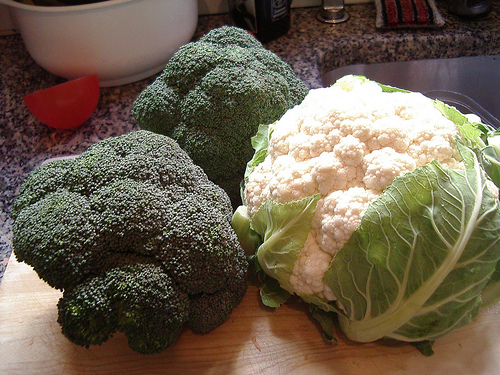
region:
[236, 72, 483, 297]
white florets of fresh cauliflower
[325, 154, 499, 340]
a dark leaf hugs the cauliflower head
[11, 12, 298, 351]
two firm heads of broccoli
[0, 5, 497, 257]
a granite counter top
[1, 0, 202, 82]
a large white bowl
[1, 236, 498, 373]
vegetables sit on a cutting board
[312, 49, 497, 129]
back wall of a kitchen sink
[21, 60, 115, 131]
a red wedge on the counter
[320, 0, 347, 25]
a part of the faucet fixture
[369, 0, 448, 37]
a plastic scrubber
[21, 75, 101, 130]
a tomato half on the counter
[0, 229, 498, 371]
a cutting board on the counter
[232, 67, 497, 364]
a cauliflower on the cutting board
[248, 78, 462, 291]
the cauliflower is white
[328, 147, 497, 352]
the leaves are green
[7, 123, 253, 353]
a broccoli chunk on the cutting board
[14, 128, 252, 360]
the broccoli is green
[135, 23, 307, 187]
a broccoli stem on the counter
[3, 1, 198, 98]
a white bowl by the tomato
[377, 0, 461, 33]
a sponge behind the sink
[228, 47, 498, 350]
an open piece of cauliflower.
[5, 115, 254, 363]
a large head of broccoli.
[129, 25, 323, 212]
broccoli on a table.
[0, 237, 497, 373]
a table with vegetables on it.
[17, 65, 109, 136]
a piece of food on a counter.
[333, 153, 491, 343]
a leaf on cauli flower.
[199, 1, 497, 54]
a granite counter top.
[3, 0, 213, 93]
A large white bowl on a counter.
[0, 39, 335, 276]
a black and white speckled counter top.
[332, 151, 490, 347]
a vein in a leaf.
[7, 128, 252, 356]
a green head of broccoli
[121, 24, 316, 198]
a green head of broccoli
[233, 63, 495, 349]
a head of colliflower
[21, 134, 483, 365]
a wooden cutting board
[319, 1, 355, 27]
a soap dispenser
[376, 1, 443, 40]
a cleaning sponge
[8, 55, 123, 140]
a plastic egg shell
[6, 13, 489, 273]
granite counter top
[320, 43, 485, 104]
a deep metal sink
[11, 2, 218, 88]
a round white plastic bowl